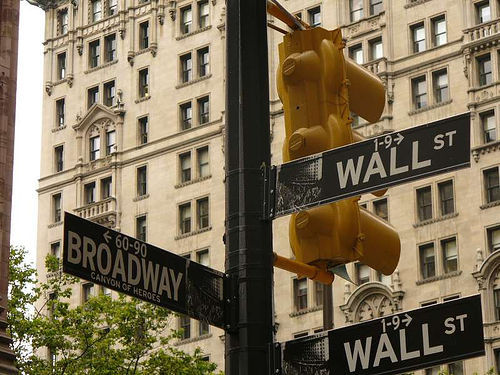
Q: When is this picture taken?
A: Daytime.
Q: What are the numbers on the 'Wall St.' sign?
A: 1-9.